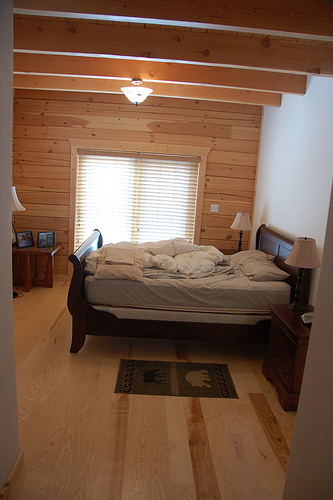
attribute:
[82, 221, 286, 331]
bed — unmade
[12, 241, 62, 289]
table — brown, wooden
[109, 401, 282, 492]
floor — wooden